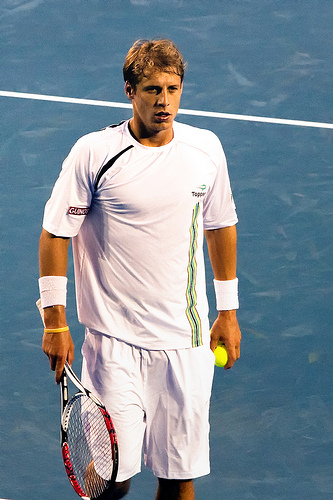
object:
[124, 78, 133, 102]
ear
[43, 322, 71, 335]
yellow bracelet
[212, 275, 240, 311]
wrist band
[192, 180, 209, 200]
logo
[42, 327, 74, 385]
hand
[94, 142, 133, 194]
black stripe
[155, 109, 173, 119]
mouth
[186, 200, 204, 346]
rainbow stripe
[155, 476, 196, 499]
leg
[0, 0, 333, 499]
court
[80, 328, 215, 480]
shorts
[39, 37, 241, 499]
man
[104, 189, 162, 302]
white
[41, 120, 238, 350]
white tshirt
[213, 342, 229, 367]
tennis ball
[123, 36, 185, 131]
head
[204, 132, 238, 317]
arm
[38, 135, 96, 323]
arm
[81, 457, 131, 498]
leg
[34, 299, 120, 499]
racket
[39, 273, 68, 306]
band